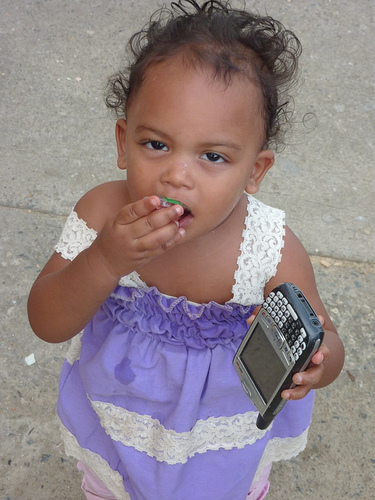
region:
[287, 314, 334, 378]
she is holding the phone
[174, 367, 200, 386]
the dress is purple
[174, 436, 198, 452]
the lace is white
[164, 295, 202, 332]
the dress has ruffles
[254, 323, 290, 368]
the phone is upside down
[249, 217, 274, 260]
the strap is made of lace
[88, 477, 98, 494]
the pants are pink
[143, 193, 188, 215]
she is eating ice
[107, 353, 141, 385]
the dress has a wet spot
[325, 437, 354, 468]
the sidewalk is gray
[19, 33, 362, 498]
Little girl wearing a purple dress.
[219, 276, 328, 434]
Black cell phone.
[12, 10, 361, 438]
Young girl holding a black cell phone.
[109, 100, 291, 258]
Girl eating something.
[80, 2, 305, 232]
Girl with black curly hair.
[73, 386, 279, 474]
Band of lace sewn to the girls dress.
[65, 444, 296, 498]
Purple shorts on the young girl.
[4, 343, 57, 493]
Ground made of cement.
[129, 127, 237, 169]
Dark brown eyes on the young girl.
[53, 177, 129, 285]
Lace strap falling the girls shoulder.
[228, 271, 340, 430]
child holding a cellphone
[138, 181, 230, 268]
child eating something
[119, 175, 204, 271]
child putting something in mouth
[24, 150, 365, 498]
child wearing a dress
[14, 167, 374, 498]
child wearing a purple dress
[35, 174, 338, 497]
purple and white dress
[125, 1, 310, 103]
curly black hair of child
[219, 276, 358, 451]
girl holding a cellphone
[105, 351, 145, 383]
wet spot in purple dress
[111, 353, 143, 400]
stain on girl's dress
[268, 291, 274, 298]
white button on phone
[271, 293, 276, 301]
white button on phone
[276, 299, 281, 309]
white button on phone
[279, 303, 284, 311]
white button on phone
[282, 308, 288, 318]
white button on phone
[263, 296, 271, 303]
white button on phone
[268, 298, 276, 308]
white button on phone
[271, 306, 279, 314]
white button on phone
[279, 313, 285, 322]
white button on phone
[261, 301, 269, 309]
white button on phone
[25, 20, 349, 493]
the child holding the cellphone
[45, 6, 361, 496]
the child eating candy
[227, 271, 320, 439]
the cellphone in the hand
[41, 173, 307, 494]
the dress on the child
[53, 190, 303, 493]
the dress is purple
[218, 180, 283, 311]
strap of dress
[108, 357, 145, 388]
the stain on the dress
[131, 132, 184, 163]
eye of the child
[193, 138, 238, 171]
eye of the child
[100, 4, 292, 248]
the head of the child